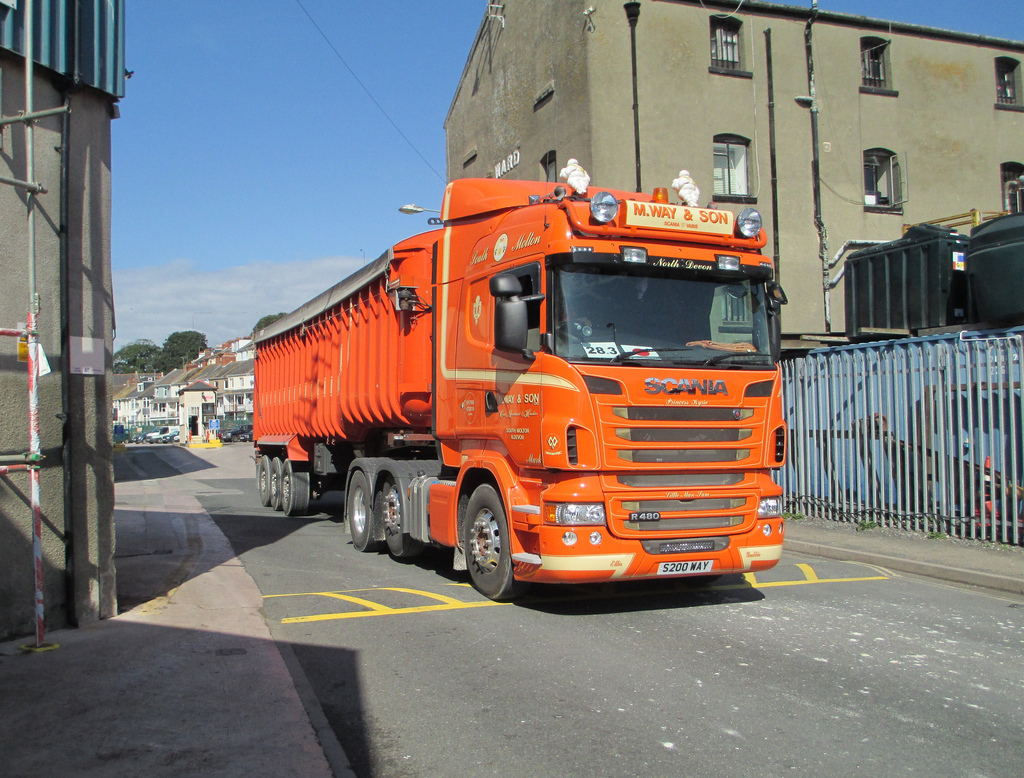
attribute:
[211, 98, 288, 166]
sky — blue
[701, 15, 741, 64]
window — glass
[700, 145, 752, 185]
window — glass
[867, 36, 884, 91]
window — glass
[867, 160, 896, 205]
window — glass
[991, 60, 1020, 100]
window — glass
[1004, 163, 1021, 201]
window — glass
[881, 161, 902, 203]
window — glass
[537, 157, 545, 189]
window — glass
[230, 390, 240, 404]
window — glass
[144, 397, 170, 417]
window — glass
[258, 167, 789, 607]
dump truck — large, orange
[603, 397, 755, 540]
grill — front-facing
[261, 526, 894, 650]
lines — yellow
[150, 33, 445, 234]
sky — Blue 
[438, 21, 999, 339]
building — large , gray 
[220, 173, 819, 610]
truck — Orange 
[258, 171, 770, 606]
truck — Orange 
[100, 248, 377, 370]
clouds — white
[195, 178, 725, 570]
truck — orange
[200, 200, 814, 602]
truck — orange